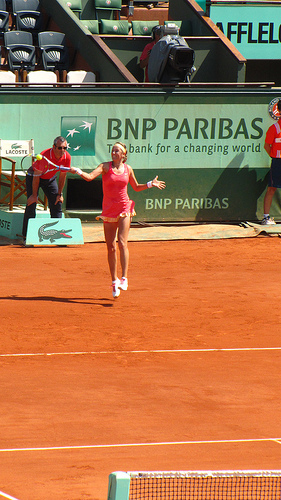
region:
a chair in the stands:
[35, 27, 73, 70]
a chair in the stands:
[1, 27, 36, 71]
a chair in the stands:
[9, 0, 39, 30]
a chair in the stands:
[0, 0, 6, 21]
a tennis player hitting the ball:
[17, 131, 169, 297]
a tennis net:
[94, 462, 275, 493]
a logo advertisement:
[29, 217, 75, 238]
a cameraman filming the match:
[133, 20, 194, 84]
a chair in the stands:
[89, 0, 115, 20]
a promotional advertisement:
[104, 113, 265, 160]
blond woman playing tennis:
[77, 128, 162, 305]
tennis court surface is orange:
[68, 309, 223, 396]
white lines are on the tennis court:
[50, 431, 176, 454]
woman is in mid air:
[86, 268, 158, 325]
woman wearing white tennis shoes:
[102, 267, 135, 311]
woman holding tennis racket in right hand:
[16, 147, 83, 179]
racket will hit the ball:
[19, 150, 75, 180]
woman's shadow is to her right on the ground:
[21, 215, 137, 323]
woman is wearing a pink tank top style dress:
[101, 162, 151, 227]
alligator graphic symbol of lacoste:
[15, 209, 84, 246]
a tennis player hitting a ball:
[20, 145, 176, 299]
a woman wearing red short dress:
[94, 140, 147, 221]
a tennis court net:
[94, 452, 277, 496]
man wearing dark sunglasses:
[47, 137, 74, 154]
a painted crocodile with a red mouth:
[33, 219, 81, 241]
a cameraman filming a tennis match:
[141, 16, 205, 91]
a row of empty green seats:
[81, 12, 150, 33]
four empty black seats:
[1, 6, 68, 70]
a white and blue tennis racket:
[21, 149, 70, 181]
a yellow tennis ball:
[35, 151, 44, 164]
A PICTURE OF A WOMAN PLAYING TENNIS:
[20, 133, 174, 301]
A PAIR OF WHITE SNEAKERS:
[102, 274, 131, 299]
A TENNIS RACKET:
[18, 150, 74, 179]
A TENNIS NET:
[105, 466, 280, 497]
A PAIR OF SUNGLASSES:
[50, 143, 77, 153]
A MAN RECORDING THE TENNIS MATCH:
[133, 21, 210, 90]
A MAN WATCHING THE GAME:
[16, 135, 87, 240]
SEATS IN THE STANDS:
[1, 9, 115, 83]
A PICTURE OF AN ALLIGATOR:
[21, 216, 91, 248]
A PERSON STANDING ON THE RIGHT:
[257, 96, 278, 230]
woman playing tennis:
[19, 140, 168, 306]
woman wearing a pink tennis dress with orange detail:
[90, 158, 138, 226]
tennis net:
[103, 461, 278, 497]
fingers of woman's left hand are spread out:
[149, 171, 163, 189]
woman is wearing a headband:
[102, 137, 125, 159]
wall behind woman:
[0, 81, 278, 222]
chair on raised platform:
[0, 137, 62, 237]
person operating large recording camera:
[131, 17, 202, 84]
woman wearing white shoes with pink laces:
[105, 260, 128, 295]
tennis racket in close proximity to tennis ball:
[19, 148, 70, 180]